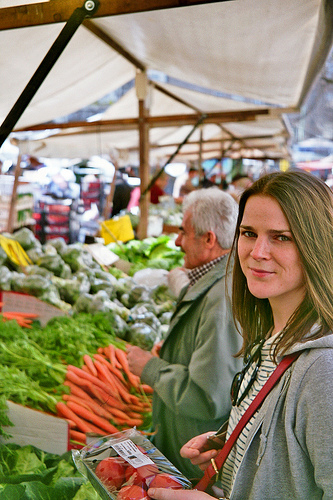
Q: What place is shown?
A: It is a market.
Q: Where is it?
A: This is at the market.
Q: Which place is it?
A: It is a market.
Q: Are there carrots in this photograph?
A: Yes, there is a carrot.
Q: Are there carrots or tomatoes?
A: Yes, there is a carrot.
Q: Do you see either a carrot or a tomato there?
A: Yes, there is a carrot.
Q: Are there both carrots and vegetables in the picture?
A: Yes, there are both a carrot and vegetables.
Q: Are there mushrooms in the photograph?
A: No, there are no mushrooms.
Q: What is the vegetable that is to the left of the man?
A: The vegetable is a carrot.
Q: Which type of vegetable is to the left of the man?
A: The vegetable is a carrot.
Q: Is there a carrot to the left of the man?
A: Yes, there is a carrot to the left of the man.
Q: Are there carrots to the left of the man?
A: Yes, there is a carrot to the left of the man.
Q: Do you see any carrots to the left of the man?
A: Yes, there is a carrot to the left of the man.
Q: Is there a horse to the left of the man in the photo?
A: No, there is a carrot to the left of the man.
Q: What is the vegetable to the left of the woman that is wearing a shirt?
A: The vegetable is a carrot.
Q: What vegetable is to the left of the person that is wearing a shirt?
A: The vegetable is a carrot.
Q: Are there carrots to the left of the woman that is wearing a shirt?
A: Yes, there is a carrot to the left of the woman.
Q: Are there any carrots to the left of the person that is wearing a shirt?
A: Yes, there is a carrot to the left of the woman.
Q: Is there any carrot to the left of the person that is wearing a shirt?
A: Yes, there is a carrot to the left of the woman.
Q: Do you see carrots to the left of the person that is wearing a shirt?
A: Yes, there is a carrot to the left of the woman.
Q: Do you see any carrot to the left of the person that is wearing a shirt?
A: Yes, there is a carrot to the left of the woman.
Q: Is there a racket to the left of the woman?
A: No, there is a carrot to the left of the woman.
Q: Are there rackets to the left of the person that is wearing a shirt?
A: No, there is a carrot to the left of the woman.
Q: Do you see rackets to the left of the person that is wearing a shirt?
A: No, there is a carrot to the left of the woman.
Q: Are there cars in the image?
A: No, there are no cars.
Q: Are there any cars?
A: No, there are no cars.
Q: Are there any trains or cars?
A: No, there are no cars or trains.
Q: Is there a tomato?
A: Yes, there is a tomato.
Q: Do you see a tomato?
A: Yes, there is a tomato.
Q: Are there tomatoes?
A: Yes, there is a tomato.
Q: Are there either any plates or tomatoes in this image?
A: Yes, there is a tomato.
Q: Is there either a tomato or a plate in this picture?
A: Yes, there is a tomato.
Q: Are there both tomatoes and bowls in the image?
A: No, there is a tomato but no bowls.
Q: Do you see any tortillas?
A: No, there are no tortillas.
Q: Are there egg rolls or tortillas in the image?
A: No, there are no tortillas or egg rolls.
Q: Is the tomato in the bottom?
A: Yes, the tomato is in the bottom of the image.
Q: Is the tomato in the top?
A: No, the tomato is in the bottom of the image.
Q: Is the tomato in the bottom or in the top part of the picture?
A: The tomato is in the bottom of the image.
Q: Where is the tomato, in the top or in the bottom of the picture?
A: The tomato is in the bottom of the image.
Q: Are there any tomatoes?
A: Yes, there is a tomato.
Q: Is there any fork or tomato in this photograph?
A: Yes, there is a tomato.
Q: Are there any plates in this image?
A: No, there are no plates.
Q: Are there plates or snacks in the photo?
A: No, there are no plates or snacks.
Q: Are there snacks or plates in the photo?
A: No, there are no plates or snacks.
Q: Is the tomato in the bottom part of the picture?
A: Yes, the tomato is in the bottom of the image.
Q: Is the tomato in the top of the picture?
A: No, the tomato is in the bottom of the image.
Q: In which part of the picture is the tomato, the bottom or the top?
A: The tomato is in the bottom of the image.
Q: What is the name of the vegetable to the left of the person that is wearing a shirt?
A: The vegetable is a tomato.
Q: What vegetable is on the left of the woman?
A: The vegetable is a tomato.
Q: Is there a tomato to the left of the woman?
A: Yes, there is a tomato to the left of the woman.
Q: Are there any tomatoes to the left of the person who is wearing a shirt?
A: Yes, there is a tomato to the left of the woman.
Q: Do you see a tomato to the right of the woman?
A: No, the tomato is to the left of the woman.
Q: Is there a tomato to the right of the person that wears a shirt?
A: No, the tomato is to the left of the woman.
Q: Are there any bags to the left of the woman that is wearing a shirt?
A: No, there is a tomato to the left of the woman.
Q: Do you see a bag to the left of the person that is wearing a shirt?
A: No, there is a tomato to the left of the woman.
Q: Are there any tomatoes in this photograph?
A: Yes, there is a tomato.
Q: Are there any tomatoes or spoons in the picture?
A: Yes, there is a tomato.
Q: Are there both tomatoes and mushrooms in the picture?
A: No, there is a tomato but no mushrooms.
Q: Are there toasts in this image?
A: No, there are no toasts.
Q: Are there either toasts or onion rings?
A: No, there are no toasts or onion rings.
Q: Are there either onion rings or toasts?
A: No, there are no toasts or onion rings.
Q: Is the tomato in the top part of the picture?
A: No, the tomato is in the bottom of the image.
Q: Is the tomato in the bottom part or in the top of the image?
A: The tomato is in the bottom of the image.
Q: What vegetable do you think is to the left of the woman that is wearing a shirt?
A: The vegetable is a tomato.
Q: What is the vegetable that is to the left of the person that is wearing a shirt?
A: The vegetable is a tomato.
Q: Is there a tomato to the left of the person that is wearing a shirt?
A: Yes, there is a tomato to the left of the woman.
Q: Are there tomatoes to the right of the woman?
A: No, the tomato is to the left of the woman.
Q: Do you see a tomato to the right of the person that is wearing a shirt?
A: No, the tomato is to the left of the woman.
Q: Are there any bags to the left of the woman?
A: No, there is a tomato to the left of the woman.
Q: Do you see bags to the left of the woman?
A: No, there is a tomato to the left of the woman.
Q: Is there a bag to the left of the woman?
A: No, there is a tomato to the left of the woman.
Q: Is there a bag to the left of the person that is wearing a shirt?
A: No, there is a tomato to the left of the woman.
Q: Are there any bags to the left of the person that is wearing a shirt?
A: No, there is a tomato to the left of the woman.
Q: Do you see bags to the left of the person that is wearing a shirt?
A: No, there is a tomato to the left of the woman.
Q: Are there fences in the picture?
A: No, there are no fences.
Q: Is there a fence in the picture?
A: No, there are no fences.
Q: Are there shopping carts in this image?
A: No, there are no shopping carts.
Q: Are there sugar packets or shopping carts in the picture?
A: No, there are no shopping carts or sugar packets.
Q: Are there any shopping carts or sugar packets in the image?
A: No, there are no shopping carts or sugar packets.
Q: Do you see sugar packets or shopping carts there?
A: No, there are no shopping carts or sugar packets.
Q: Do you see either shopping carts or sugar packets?
A: No, there are no shopping carts or sugar packets.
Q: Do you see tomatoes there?
A: Yes, there is a tomato.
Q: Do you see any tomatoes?
A: Yes, there is a tomato.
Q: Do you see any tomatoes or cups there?
A: Yes, there is a tomato.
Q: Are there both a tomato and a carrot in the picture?
A: Yes, there are both a tomato and a carrot.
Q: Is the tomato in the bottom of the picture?
A: Yes, the tomato is in the bottom of the image.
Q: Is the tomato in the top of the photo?
A: No, the tomato is in the bottom of the image.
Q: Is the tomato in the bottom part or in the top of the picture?
A: The tomato is in the bottom of the image.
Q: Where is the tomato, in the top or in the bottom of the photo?
A: The tomato is in the bottom of the image.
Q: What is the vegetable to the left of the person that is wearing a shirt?
A: The vegetable is a tomato.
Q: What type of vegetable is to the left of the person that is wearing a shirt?
A: The vegetable is a tomato.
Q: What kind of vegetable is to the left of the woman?
A: The vegetable is a tomato.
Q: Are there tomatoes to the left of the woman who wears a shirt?
A: Yes, there is a tomato to the left of the woman.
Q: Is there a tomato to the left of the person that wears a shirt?
A: Yes, there is a tomato to the left of the woman.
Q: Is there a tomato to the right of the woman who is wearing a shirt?
A: No, the tomato is to the left of the woman.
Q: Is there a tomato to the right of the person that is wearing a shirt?
A: No, the tomato is to the left of the woman.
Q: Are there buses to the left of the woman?
A: No, there is a tomato to the left of the woman.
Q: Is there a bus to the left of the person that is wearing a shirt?
A: No, there is a tomato to the left of the woman.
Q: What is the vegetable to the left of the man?
A: The vegetable is a tomato.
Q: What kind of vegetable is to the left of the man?
A: The vegetable is a tomato.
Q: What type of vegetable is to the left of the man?
A: The vegetable is a tomato.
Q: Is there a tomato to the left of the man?
A: Yes, there is a tomato to the left of the man.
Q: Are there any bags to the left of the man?
A: No, there is a tomato to the left of the man.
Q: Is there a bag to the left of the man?
A: No, there is a tomato to the left of the man.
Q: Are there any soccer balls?
A: No, there are no soccer balls.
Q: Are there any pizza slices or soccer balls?
A: No, there are no soccer balls or pizza slices.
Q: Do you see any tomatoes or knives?
A: Yes, there are tomatoes.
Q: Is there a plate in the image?
A: No, there are no plates.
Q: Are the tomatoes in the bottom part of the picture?
A: Yes, the tomatoes are in the bottom of the image.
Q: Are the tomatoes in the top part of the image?
A: No, the tomatoes are in the bottom of the image.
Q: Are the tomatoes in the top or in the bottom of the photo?
A: The tomatoes are in the bottom of the image.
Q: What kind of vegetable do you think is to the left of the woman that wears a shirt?
A: The vegetables are tomatoes.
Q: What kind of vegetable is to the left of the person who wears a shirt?
A: The vegetables are tomatoes.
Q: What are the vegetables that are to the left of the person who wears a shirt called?
A: The vegetables are tomatoes.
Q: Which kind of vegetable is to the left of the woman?
A: The vegetables are tomatoes.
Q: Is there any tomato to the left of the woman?
A: Yes, there are tomatoes to the left of the woman.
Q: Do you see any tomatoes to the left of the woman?
A: Yes, there are tomatoes to the left of the woman.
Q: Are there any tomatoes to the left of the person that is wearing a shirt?
A: Yes, there are tomatoes to the left of the woman.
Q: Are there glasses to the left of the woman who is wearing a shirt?
A: No, there are tomatoes to the left of the woman.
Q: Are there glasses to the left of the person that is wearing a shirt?
A: No, there are tomatoes to the left of the woman.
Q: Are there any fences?
A: No, there are no fences.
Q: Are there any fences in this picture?
A: No, there are no fences.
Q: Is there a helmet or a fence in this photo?
A: No, there are no fences or helmets.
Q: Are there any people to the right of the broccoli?
A: Yes, there is a person to the right of the broccoli.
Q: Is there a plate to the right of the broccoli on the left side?
A: No, there is a person to the right of the broccoli.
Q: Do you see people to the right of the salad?
A: Yes, there is a person to the right of the salad.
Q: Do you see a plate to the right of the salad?
A: No, there is a person to the right of the salad.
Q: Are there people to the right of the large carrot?
A: Yes, there is a person to the right of the carrot.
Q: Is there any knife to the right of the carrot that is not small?
A: No, there is a person to the right of the carrot.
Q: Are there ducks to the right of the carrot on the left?
A: No, there is a person to the right of the carrot.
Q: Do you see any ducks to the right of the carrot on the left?
A: No, there is a person to the right of the carrot.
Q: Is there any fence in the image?
A: No, there are no fences.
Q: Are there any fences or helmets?
A: No, there are no fences or helmets.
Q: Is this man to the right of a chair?
A: No, the man is to the right of a carrot.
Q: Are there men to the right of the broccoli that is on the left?
A: Yes, there is a man to the right of the broccoli.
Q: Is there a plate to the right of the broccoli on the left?
A: No, there is a man to the right of the broccoli.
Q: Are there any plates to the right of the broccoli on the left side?
A: No, there is a man to the right of the broccoli.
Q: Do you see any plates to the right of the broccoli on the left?
A: No, there is a man to the right of the broccoli.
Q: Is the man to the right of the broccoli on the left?
A: Yes, the man is to the right of the broccoli.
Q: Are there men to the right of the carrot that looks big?
A: Yes, there is a man to the right of the carrot.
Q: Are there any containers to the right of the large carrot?
A: No, there is a man to the right of the carrot.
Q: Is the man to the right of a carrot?
A: Yes, the man is to the right of a carrot.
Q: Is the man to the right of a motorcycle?
A: No, the man is to the right of a carrot.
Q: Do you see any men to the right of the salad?
A: Yes, there is a man to the right of the salad.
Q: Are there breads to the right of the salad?
A: No, there is a man to the right of the salad.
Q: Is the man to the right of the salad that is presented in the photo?
A: Yes, the man is to the right of the salad.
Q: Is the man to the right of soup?
A: No, the man is to the right of the salad.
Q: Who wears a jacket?
A: The man wears a jacket.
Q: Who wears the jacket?
A: The man wears a jacket.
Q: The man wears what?
A: The man wears a jacket.